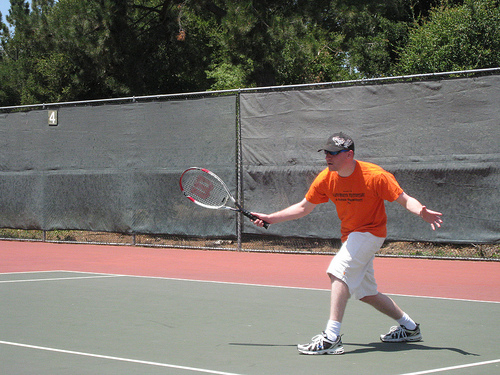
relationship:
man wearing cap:
[249, 131, 443, 356] [317, 130, 353, 152]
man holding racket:
[234, 107, 420, 372] [167, 154, 282, 234]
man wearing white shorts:
[249, 131, 443, 356] [330, 228, 385, 304]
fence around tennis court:
[5, 62, 497, 267] [57, 60, 448, 366]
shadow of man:
[426, 322, 483, 373] [217, 75, 479, 329]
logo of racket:
[192, 174, 213, 201] [179, 164, 271, 231]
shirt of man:
[308, 170, 406, 227] [294, 101, 413, 332]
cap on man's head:
[317, 132, 355, 152] [297, 118, 365, 210]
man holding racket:
[249, 131, 443, 356] [158, 153, 276, 240]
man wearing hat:
[249, 131, 443, 356] [314, 127, 356, 156]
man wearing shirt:
[249, 131, 443, 356] [304, 157, 405, 244]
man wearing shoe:
[249, 131, 443, 356] [296, 330, 344, 355]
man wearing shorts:
[249, 131, 443, 356] [325, 232, 386, 301]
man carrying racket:
[249, 131, 443, 356] [180, 157, 271, 235]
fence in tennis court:
[5, 62, 497, 267] [46, 64, 419, 347]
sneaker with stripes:
[276, 309, 441, 364] [297, 327, 349, 356]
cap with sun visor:
[315, 126, 363, 157] [308, 128, 378, 179]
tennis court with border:
[4, 270, 497, 374] [0, 231, 499, 305]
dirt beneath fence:
[1, 224, 498, 264] [1, 63, 498, 228]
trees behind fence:
[4, 2, 496, 112] [5, 62, 497, 267]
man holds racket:
[249, 131, 443, 356] [179, 166, 271, 230]